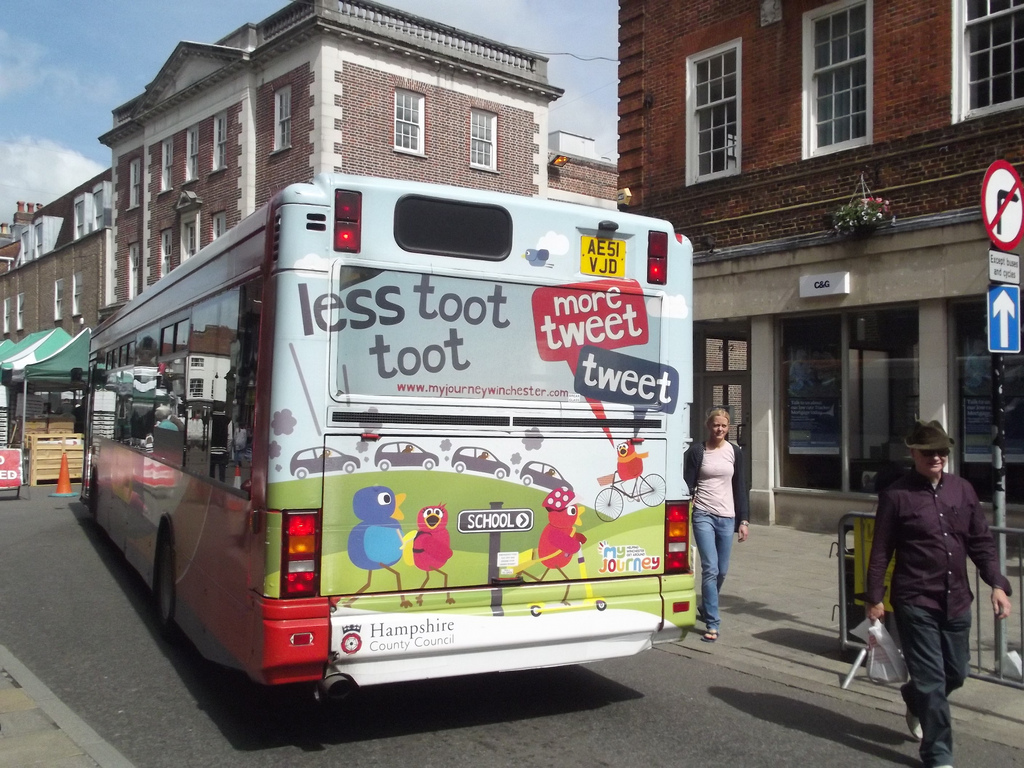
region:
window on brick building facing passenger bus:
[682, 38, 742, 187]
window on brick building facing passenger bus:
[803, 36, 870, 160]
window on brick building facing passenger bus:
[957, 36, 1022, 121]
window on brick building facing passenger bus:
[465, 102, 499, 169]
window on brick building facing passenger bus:
[393, 86, 427, 160]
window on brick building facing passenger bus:
[269, 80, 294, 153]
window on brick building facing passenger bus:
[212, 109, 232, 171]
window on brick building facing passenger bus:
[183, 126, 199, 184]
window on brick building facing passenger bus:
[156, 137, 176, 195]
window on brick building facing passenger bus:
[125, 155, 145, 209]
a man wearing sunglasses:
[918, 441, 963, 462]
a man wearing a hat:
[912, 418, 948, 457]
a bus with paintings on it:
[57, 178, 734, 722]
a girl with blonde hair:
[708, 395, 734, 446]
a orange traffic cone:
[48, 444, 81, 499]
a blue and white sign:
[983, 282, 1021, 344]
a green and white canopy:
[8, 308, 86, 397]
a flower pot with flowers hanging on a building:
[831, 174, 892, 244]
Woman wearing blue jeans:
[680, 404, 754, 646]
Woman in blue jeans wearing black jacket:
[686, 403, 756, 648]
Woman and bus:
[74, 165, 757, 726]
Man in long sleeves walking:
[832, 416, 1019, 767]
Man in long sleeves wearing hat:
[832, 413, 1019, 767]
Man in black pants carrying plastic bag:
[835, 415, 1016, 764]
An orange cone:
[42, 441, 77, 498]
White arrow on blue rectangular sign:
[983, 280, 1022, 357]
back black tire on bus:
[146, 514, 182, 635]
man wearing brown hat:
[863, 412, 1007, 766]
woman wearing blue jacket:
[689, 403, 753, 650]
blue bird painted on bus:
[348, 478, 409, 586]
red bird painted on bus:
[409, 504, 455, 577]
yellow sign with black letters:
[582, 238, 628, 281]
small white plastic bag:
[863, 614, 908, 690]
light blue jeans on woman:
[686, 505, 731, 630]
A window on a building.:
[385, 83, 431, 164]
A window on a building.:
[468, 106, 498, 168]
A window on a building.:
[680, 48, 753, 178]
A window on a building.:
[272, 86, 298, 153]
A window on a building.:
[208, 109, 235, 164]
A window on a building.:
[185, 121, 198, 183]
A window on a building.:
[154, 133, 173, 194]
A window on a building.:
[128, 241, 160, 298]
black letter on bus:
[291, 282, 329, 339]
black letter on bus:
[310, 284, 348, 343]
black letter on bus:
[345, 283, 377, 341]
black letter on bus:
[368, 277, 404, 341]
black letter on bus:
[415, 271, 438, 323]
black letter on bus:
[433, 289, 465, 322]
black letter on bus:
[455, 284, 491, 327]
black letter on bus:
[478, 279, 511, 343]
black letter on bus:
[365, 328, 397, 386]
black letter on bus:
[393, 342, 425, 380]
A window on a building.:
[689, 42, 762, 160]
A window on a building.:
[953, 14, 1001, 95]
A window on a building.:
[470, 98, 503, 165]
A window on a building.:
[385, 89, 424, 156]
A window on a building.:
[262, 93, 297, 155]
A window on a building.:
[202, 112, 237, 174]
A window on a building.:
[185, 128, 202, 180]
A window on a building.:
[155, 136, 175, 185]